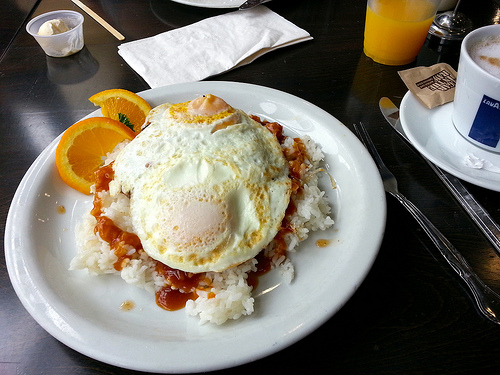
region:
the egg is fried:
[116, 96, 289, 269]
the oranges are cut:
[58, 88, 151, 196]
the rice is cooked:
[73, 120, 334, 330]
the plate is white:
[3, 75, 383, 370]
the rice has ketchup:
[71, 92, 323, 320]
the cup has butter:
[36, 7, 82, 62]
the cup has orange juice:
[364, 0, 439, 60]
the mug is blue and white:
[452, 22, 499, 154]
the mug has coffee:
[454, 25, 498, 152]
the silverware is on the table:
[359, 95, 498, 322]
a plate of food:
[4, 51, 446, 372]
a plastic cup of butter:
[13, 11, 115, 71]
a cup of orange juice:
[350, 5, 441, 59]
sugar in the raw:
[392, 51, 474, 113]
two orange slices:
[33, 78, 166, 189]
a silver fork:
[320, 108, 499, 338]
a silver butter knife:
[372, 85, 498, 237]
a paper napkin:
[112, 9, 357, 89]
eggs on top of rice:
[58, 94, 386, 335]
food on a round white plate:
[8, 63, 388, 374]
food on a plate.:
[2, 74, 405, 374]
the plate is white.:
[5, 75, 390, 353]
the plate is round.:
[1, 75, 393, 361]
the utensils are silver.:
[349, 86, 499, 318]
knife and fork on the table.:
[331, 82, 498, 320]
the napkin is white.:
[114, 6, 314, 89]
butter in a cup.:
[20, 9, 87, 56]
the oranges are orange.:
[52, 80, 153, 198]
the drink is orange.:
[361, 0, 441, 70]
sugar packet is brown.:
[389, 56, 466, 108]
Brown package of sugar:
[391, 61, 468, 118]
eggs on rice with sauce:
[76, 84, 298, 314]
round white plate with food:
[21, 79, 403, 358]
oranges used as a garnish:
[51, 87, 173, 207]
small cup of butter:
[26, 11, 107, 66]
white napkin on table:
[117, 4, 315, 94]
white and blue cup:
[451, 27, 499, 159]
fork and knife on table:
[353, 88, 493, 313]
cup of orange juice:
[356, 3, 448, 88]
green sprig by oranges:
[96, 101, 151, 141]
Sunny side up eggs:
[123, 127, 263, 273]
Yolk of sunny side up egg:
[149, 193, 225, 248]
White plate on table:
[11, 251, 68, 326]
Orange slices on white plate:
[53, 117, 110, 181]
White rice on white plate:
[183, 282, 265, 327]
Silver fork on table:
[379, 116, 430, 341]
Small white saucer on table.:
[403, 94, 498, 209]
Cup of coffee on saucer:
[456, 17, 498, 166]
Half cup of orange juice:
[358, 1, 433, 63]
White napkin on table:
[111, 17, 316, 63]